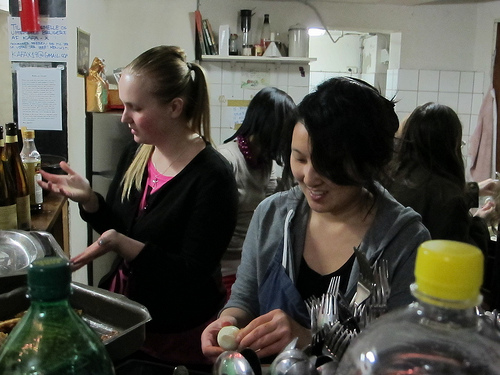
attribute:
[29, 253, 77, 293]
bottle cap — green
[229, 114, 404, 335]
woman — standing, inside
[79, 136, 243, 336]
sweater — black 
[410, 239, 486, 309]
cap — yellow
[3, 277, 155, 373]
cooking tray — silver 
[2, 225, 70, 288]
cooking tray — silver 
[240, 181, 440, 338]
jacket — gray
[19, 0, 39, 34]
hydrant — red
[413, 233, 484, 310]
top — yellow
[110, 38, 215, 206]
blonde hair — blonde 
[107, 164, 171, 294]
shirt — pink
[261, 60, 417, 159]
hair — short, black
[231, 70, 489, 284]
girl — black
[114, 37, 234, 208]
hair — blonde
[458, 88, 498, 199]
jacket — pink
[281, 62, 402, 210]
hair — black 